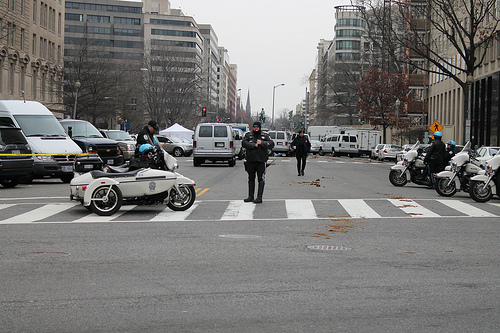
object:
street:
[1, 142, 496, 333]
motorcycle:
[68, 131, 197, 217]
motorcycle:
[468, 160, 499, 202]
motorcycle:
[387, 141, 452, 187]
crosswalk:
[1, 199, 497, 226]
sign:
[429, 120, 444, 134]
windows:
[113, 16, 141, 26]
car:
[378, 144, 398, 161]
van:
[192, 122, 238, 167]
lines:
[194, 186, 211, 197]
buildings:
[65, 0, 239, 135]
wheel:
[163, 184, 196, 211]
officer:
[242, 122, 275, 203]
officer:
[133, 118, 165, 204]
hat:
[148, 120, 159, 130]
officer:
[422, 130, 449, 187]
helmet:
[434, 131, 442, 137]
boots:
[243, 178, 255, 201]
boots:
[252, 179, 266, 203]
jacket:
[241, 131, 275, 162]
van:
[0, 98, 83, 180]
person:
[446, 140, 456, 159]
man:
[291, 129, 313, 176]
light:
[202, 106, 206, 117]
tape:
[1, 150, 98, 160]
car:
[0, 123, 35, 187]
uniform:
[242, 130, 275, 199]